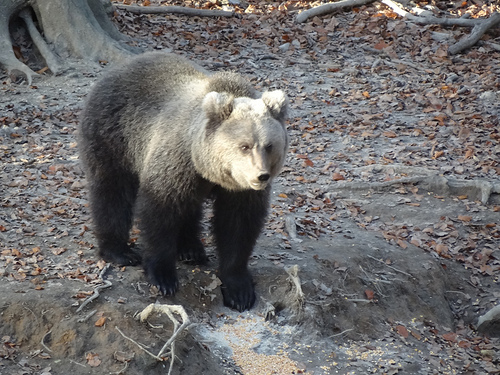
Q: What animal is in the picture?
A: The bear.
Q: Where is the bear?
A: In the wilderness.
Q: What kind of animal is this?
A: Bear.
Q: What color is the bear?
A: Brown.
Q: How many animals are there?
A: One.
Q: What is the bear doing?
A: Walking.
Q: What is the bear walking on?
A: Ground.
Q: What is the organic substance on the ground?
A: Leaves.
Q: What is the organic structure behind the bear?
A: Tree.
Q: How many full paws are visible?
A: Four.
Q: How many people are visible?
A: None.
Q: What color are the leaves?
A: Rust colored.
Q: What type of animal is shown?
A: Bear.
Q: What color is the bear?
A: Black.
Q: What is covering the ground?
A: Leaves.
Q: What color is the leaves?
A: Brown.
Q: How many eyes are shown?
A: 2.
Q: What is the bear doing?
A: Walking.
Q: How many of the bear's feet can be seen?
A: 4.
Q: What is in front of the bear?
A: A bank.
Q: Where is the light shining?
A: Bear's head.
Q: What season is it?
A: Autumn.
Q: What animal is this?
A: Bear.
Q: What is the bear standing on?
A: Dirt.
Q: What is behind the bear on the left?
A: Tree.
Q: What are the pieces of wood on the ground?
A: Sticks.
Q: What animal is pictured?
A: A bear.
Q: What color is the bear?
A: Brown.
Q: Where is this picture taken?
A: The forest.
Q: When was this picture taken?
A: Daytime.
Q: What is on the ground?
A: Leaves.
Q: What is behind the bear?
A: A tree.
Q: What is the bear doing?
A: Walking.